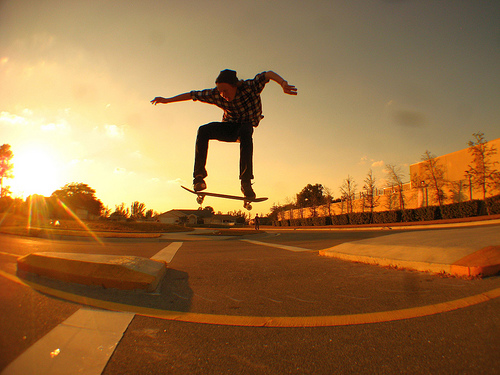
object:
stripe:
[198, 310, 389, 328]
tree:
[49, 182, 106, 217]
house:
[151, 209, 221, 226]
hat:
[215, 69, 239, 84]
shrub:
[484, 194, 500, 216]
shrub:
[414, 205, 440, 222]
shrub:
[439, 198, 484, 220]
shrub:
[373, 210, 402, 224]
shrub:
[312, 216, 330, 226]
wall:
[409, 138, 499, 190]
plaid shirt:
[190, 71, 270, 128]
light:
[0, 149, 65, 203]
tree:
[465, 131, 500, 201]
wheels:
[198, 198, 204, 204]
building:
[277, 137, 500, 227]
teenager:
[150, 69, 298, 199]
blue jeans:
[193, 122, 254, 180]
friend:
[254, 213, 261, 232]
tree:
[420, 148, 451, 207]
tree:
[386, 164, 414, 222]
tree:
[360, 168, 381, 212]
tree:
[338, 175, 358, 214]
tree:
[308, 191, 320, 217]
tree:
[292, 193, 308, 225]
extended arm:
[167, 91, 215, 103]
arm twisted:
[265, 70, 275, 82]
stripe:
[0, 273, 188, 323]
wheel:
[196, 197, 201, 201]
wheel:
[243, 203, 248, 208]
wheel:
[246, 204, 252, 210]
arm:
[252, 70, 288, 96]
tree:
[323, 185, 335, 224]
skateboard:
[180, 185, 269, 211]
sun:
[0, 152, 70, 201]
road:
[167, 233, 327, 374]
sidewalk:
[47, 227, 268, 241]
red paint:
[450, 246, 500, 278]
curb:
[305, 221, 500, 231]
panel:
[319, 227, 500, 279]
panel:
[16, 251, 167, 293]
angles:
[319, 250, 483, 279]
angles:
[16, 259, 153, 293]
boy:
[150, 69, 297, 199]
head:
[215, 78, 243, 102]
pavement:
[42, 228, 266, 241]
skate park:
[0, 137, 500, 375]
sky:
[0, 0, 150, 148]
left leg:
[238, 124, 254, 178]